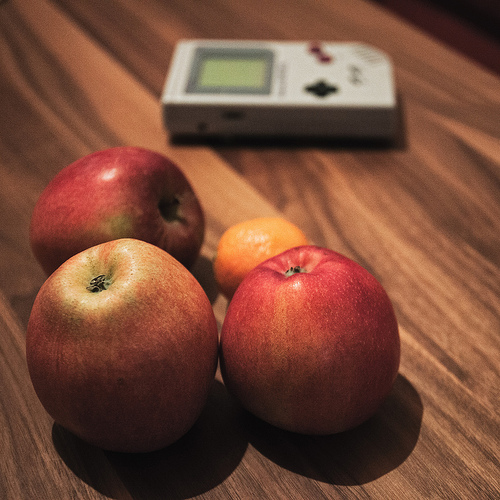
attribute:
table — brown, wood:
[3, 1, 482, 222]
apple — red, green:
[235, 245, 401, 435]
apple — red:
[14, 245, 220, 456]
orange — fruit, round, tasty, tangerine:
[219, 216, 314, 263]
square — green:
[200, 49, 266, 95]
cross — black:
[304, 79, 341, 102]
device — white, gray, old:
[162, 38, 400, 142]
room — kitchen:
[6, 5, 498, 496]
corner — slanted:
[362, 42, 390, 57]